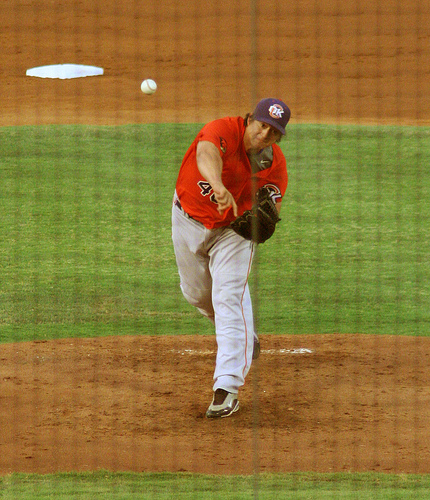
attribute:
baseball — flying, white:
[137, 72, 160, 102]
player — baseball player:
[176, 100, 292, 424]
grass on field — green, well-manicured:
[4, 133, 146, 253]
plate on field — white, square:
[29, 60, 107, 91]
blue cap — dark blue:
[258, 102, 291, 134]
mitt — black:
[234, 199, 282, 244]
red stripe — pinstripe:
[239, 237, 261, 380]